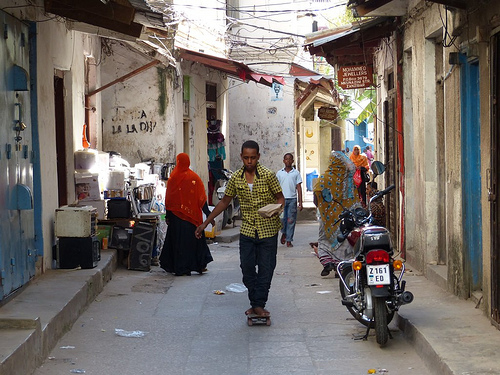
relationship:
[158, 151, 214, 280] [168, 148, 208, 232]
woman with scarf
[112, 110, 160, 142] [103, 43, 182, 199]
graffiti on wall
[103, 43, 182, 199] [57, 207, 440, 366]
wall in street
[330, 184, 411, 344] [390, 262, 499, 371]
bike parked near sidewalk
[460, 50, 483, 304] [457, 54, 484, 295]
door has trim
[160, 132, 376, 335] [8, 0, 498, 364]
people walking in area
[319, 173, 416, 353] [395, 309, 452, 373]
motorcycle on curb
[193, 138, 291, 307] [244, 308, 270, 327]
kid riding skateboard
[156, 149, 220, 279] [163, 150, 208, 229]
lady wearing orange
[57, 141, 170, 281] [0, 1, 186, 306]
pile next to building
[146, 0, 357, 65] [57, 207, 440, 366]
wires above street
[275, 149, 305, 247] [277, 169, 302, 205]
man in shirt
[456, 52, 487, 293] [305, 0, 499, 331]
doorway to building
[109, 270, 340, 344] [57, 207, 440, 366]
trash on street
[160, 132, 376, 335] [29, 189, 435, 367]
people in alley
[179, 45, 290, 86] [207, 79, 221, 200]
awning over doorway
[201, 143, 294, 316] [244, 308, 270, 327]
boy riding skateboard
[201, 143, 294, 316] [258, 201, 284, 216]
boy carrying book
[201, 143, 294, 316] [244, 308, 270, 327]
boy on skateboard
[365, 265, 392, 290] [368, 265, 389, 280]
plate with z161 ed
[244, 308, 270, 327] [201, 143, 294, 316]
skateboard used by boy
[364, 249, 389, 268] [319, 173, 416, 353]
stoplight on motorcycle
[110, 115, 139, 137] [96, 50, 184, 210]
la la wriiten on side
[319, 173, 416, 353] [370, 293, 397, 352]
motorcycle has tire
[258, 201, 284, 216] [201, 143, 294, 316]
package held by boy